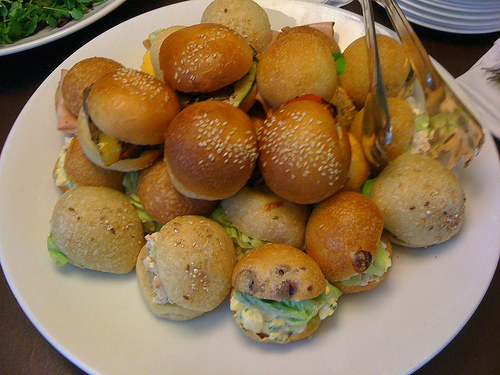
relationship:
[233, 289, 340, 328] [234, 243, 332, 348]
lettuce in sandwich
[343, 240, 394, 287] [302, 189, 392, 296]
lettuce in bread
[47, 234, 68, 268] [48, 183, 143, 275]
lettuce in bread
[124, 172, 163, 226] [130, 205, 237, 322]
lettuce in sandwich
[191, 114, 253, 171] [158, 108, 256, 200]
seeds on bun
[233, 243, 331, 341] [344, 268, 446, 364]
bread on plate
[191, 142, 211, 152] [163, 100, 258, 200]
seeds on bun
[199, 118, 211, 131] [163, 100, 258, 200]
seeds on bun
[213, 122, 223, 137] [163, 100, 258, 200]
seeds on bun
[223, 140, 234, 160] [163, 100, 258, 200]
seeds on bun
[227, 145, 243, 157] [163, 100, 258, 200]
seeds on bun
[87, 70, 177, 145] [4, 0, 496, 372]
bread on plate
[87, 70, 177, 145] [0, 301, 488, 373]
bread on plate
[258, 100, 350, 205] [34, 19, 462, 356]
bread on plate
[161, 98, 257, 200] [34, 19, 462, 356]
bread on plate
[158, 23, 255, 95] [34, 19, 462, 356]
bread on plate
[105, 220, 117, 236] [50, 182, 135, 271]
speck on bun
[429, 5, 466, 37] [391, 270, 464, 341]
stack of plates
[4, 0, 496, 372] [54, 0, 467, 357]
plate full of food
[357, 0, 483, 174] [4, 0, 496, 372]
tongs leaning on plate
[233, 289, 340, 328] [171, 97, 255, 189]
lettuce sticking out from under bread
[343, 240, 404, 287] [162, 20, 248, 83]
lettuce sticking out from under bread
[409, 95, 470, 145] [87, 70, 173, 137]
lettuce sticking out from under bread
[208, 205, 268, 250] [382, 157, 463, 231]
lettuce sticking out from under bread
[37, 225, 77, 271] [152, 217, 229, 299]
lettuce sticking out from under bread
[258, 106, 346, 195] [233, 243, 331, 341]
seeds on top of bread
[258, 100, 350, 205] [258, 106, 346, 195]
bread covered in seeds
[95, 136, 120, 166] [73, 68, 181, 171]
cheese hanging out from bun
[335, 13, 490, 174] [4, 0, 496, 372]
tongs laying on plate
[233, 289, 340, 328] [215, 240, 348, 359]
lettuce hanging out from under bread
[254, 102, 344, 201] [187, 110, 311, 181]
specks on bun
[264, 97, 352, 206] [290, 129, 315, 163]
bun covered in seeds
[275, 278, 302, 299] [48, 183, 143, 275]
dot on bread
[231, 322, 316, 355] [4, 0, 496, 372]
shadow on plate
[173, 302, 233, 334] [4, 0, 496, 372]
shadow on plate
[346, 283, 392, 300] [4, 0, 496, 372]
shadow on plate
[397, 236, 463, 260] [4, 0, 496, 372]
shadow on plate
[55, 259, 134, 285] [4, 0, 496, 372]
shadow on plate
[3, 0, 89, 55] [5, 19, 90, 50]
green lettuce on edge of plate